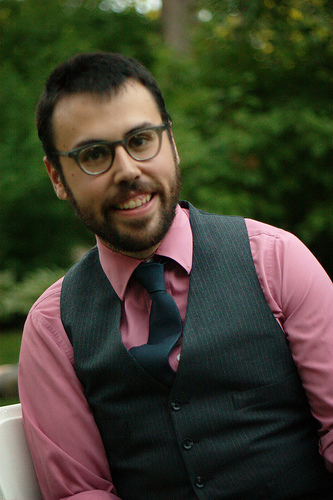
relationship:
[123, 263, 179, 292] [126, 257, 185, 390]
knot in tie